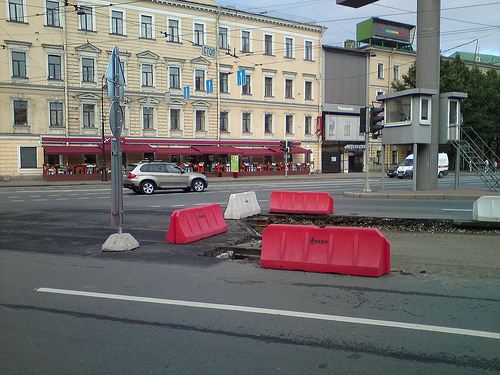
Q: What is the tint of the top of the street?
A: Black.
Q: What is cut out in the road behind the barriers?
A: A rectangular shape.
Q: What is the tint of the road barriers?
A: Red.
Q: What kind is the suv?
A: Small compact olive.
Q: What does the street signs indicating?
A: Directional order.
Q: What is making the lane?
A: A white line.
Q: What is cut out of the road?
A: A section.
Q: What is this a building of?
A: A building.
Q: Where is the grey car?
A: In the street.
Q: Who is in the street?
A: No one.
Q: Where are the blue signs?
A: Over the street.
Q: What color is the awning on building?
A: Red.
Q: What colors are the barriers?
A: Red and white.